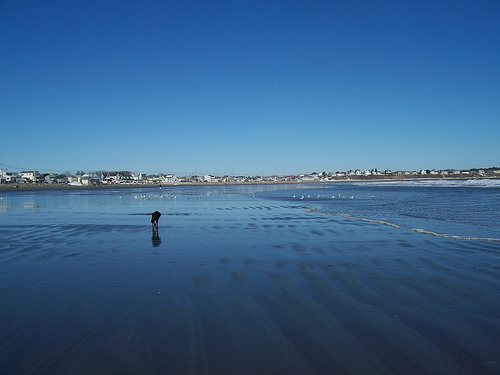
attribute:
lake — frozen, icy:
[65, 202, 469, 362]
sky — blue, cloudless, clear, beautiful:
[79, 40, 474, 142]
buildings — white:
[61, 170, 237, 190]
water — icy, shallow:
[282, 191, 478, 254]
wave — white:
[421, 177, 498, 203]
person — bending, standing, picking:
[147, 200, 173, 246]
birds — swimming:
[287, 185, 365, 207]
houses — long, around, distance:
[338, 162, 485, 181]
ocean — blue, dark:
[233, 183, 491, 327]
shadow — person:
[236, 210, 372, 236]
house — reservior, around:
[16, 168, 57, 191]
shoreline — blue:
[73, 185, 345, 200]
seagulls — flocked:
[131, 186, 282, 205]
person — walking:
[156, 180, 169, 191]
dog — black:
[13, 182, 44, 196]